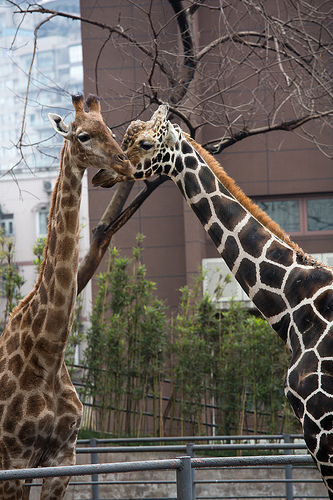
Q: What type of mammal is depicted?
A: Giraffe.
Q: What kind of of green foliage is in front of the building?
A: Bamboo.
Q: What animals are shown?
A: Giraffes.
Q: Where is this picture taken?
A: Zoo.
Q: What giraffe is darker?
A: Right one.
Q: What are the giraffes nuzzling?
A: Their faces.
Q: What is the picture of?
A: Two giraffes.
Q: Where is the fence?
A: Between the two giraffes.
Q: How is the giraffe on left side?
A: Skin has brown patches in a pattern.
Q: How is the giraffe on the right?
A: The giraffe on right has brownish black patches on skin in a pattern.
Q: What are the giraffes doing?
A: Standing tall opposite each other with their heads near each other.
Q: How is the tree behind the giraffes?
A: The tree is tall, leafless and dry.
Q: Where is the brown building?
A: Behind the giraffe enclosure.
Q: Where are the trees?
A: Along the edge of the enclosure.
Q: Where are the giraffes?
A: In a zoo.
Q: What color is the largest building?
A: Brown.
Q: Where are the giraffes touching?
A: On the face.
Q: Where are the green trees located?
A: Behind the giraffes.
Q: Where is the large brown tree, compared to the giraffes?
A: Behind the giraffes.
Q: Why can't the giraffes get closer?
A: A fence between them.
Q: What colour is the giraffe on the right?
A: Brown and white.